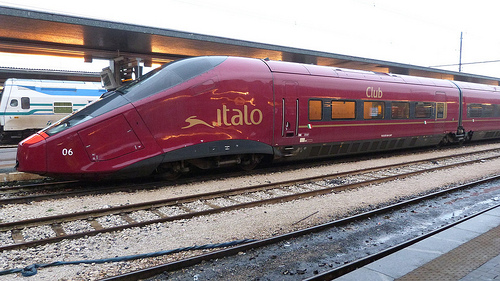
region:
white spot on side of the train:
[299, 119, 321, 136]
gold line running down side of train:
[312, 115, 453, 128]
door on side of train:
[283, 92, 304, 145]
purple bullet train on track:
[42, 51, 467, 170]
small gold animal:
[177, 109, 232, 137]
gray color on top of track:
[117, 14, 250, 46]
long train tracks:
[201, 181, 402, 199]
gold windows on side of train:
[327, 88, 363, 124]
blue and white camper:
[5, 75, 85, 120]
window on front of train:
[89, 81, 158, 114]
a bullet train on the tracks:
[0, 48, 490, 208]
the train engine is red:
[12, 53, 273, 180]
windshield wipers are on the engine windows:
[78, 70, 173, 116]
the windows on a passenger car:
[305, 93, 451, 128]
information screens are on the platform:
[98, 63, 143, 90]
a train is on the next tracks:
[2, 63, 122, 146]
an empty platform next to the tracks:
[315, 199, 495, 279]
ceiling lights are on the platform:
[7, 23, 499, 84]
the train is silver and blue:
[3, 73, 111, 135]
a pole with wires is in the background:
[449, 21, 470, 77]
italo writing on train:
[211, 97, 267, 136]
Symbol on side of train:
[177, 107, 213, 137]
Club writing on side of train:
[360, 82, 388, 102]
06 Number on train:
[56, 144, 77, 160]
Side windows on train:
[302, 92, 498, 132]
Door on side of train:
[277, 75, 304, 150]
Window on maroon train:
[35, 49, 234, 144]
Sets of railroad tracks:
[0, 139, 495, 279]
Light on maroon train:
[15, 124, 50, 156]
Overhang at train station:
[0, 2, 499, 92]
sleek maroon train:
[10, 72, 492, 178]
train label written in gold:
[181, 102, 259, 128]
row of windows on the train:
[304, 100, 489, 123]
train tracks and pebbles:
[86, 145, 468, 250]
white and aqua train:
[5, 75, 109, 135]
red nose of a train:
[16, 129, 48, 148]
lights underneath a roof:
[14, 21, 169, 63]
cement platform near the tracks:
[415, 202, 491, 279]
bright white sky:
[259, 7, 485, 72]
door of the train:
[271, 77, 305, 137]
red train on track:
[61, 50, 481, 146]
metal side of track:
[175, 253, 206, 266]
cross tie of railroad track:
[116, 210, 138, 234]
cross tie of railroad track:
[87, 218, 107, 236]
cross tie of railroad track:
[177, 203, 199, 220]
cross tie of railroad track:
[204, 198, 232, 218]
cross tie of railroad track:
[245, 190, 265, 202]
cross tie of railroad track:
[278, 183, 295, 198]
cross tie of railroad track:
[298, 181, 313, 193]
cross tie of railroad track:
[311, 179, 326, 191]